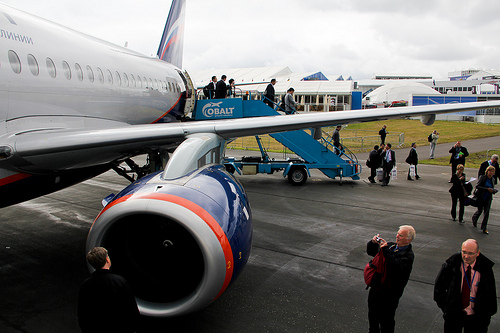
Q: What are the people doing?
A: Exiting the aircraft.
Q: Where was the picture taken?
A: An airport.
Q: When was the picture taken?
A: Afternoon.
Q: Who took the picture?
A: A tourist.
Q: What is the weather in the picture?
A: Cloudy.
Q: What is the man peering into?
A: The engine.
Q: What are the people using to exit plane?
A: Staircase.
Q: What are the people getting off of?
A: A plane.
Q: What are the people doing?
A: Walking off a plane.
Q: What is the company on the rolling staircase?
A: Cobalt.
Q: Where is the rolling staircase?
A: Next to the plane.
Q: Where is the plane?
A: Airport.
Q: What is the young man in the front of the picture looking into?
A: A plane engine.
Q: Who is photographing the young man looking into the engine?
A: Older man with a red backpack.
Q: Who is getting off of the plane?
A: Passengers.